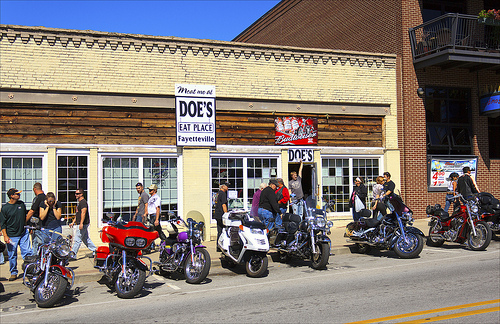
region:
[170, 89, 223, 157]
a sign on the side of a building.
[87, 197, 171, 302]
a red parked motorcycle.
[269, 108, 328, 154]
a sign on the front of a building.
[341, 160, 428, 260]
a parked motorcycle near a building.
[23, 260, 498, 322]
a paved road with double yellow lines.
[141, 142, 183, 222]
a window on the front of a building.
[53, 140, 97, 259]
a doorway on the side of a building.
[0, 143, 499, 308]
A gang of bikers in front of a store.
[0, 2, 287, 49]
a section of clear blue sky.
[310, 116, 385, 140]
a brown border on a store front.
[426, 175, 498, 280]
motorcycle parked in street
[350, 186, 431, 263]
motorcycle parked in street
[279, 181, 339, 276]
motorcycle parked in street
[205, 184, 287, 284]
motorcycle parked in street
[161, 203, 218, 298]
motorcycle parked in street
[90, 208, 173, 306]
motorcycle parked in street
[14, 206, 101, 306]
motorcycle parked in street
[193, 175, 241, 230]
people standing on sidewalk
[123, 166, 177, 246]
people standing on sidewalk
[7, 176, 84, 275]
people standing on sidewalk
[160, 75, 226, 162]
white sign with black lettering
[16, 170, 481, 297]
bunch of motorcycles parked on the street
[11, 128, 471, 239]
people walking on sidewalk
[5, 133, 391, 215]
row on windows on building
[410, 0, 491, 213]
tall red brick building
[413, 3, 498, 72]
black metal patio attached to building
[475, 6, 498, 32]
flower pot attached to metal patio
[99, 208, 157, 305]
red motorcycle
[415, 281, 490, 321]
double yellow lines painted in street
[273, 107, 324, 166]
signs above business entrance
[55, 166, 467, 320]
many motorbikes outside does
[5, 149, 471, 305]
people walking on the sidewalk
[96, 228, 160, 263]
the motorcycle is red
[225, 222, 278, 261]
the motorcycle is white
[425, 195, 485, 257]
the motorcycle is red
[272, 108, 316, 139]
the sign is red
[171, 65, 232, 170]
the sign is white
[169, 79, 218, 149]
the sign is black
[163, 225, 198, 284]
the bike is purple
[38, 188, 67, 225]
he looks very surprised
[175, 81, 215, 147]
A white sign outside a building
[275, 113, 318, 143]
A beer banner outside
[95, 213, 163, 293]
A red motorcycle parked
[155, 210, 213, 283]
A purple motorcycle parked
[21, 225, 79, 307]
A chopper bike parked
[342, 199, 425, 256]
A blue motorcycle parked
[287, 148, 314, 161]
A white sign with Doe's written on it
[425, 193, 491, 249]
A cherry red motorcycle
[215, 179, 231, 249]
A man wearing all black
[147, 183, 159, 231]
A man wearing a white shirt